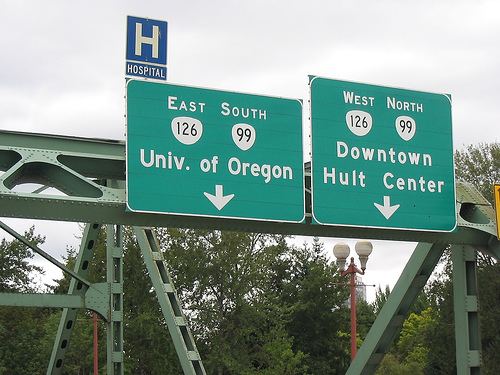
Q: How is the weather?
A: It is cloudy.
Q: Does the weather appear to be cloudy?
A: Yes, it is cloudy.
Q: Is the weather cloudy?
A: Yes, it is cloudy.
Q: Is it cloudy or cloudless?
A: It is cloudy.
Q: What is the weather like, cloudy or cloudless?
A: It is cloudy.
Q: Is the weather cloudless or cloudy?
A: It is cloudy.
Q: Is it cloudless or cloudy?
A: It is cloudy.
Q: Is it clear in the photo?
A: No, it is cloudy.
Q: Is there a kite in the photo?
A: No, there are no kites.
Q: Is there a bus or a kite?
A: No, there are no kites or buses.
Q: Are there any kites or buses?
A: No, there are no kites or buses.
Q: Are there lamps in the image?
A: Yes, there is a lamp.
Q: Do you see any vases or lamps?
A: Yes, there is a lamp.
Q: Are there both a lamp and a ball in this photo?
A: No, there is a lamp but no balls.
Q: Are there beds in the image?
A: No, there are no beds.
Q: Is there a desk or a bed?
A: No, there are no beds or desks.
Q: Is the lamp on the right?
A: Yes, the lamp is on the right of the image.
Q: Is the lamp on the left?
A: No, the lamp is on the right of the image.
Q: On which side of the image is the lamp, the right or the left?
A: The lamp is on the right of the image.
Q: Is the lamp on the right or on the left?
A: The lamp is on the right of the image.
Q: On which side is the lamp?
A: The lamp is on the right of the image.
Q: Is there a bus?
A: No, there are no buses.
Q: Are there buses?
A: No, there are no buses.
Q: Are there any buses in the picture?
A: No, there are no buses.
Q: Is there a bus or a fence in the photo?
A: No, there are no buses or fences.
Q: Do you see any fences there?
A: No, there are no fences.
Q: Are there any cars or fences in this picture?
A: No, there are no fences or cars.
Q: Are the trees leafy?
A: Yes, the trees are leafy.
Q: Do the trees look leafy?
A: Yes, the trees are leafy.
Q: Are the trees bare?
A: No, the trees are leafy.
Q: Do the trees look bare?
A: No, the trees are leafy.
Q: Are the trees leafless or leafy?
A: The trees are leafy.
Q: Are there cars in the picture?
A: No, there are no cars.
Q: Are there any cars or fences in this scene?
A: No, there are no cars or fences.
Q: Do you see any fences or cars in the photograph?
A: No, there are no cars or fences.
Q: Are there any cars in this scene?
A: No, there are no cars.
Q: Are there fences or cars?
A: No, there are no cars or fences.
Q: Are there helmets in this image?
A: No, there are no helmets.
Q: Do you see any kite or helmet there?
A: No, there are no helmets or kites.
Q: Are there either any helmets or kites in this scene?
A: No, there are no helmets or kites.